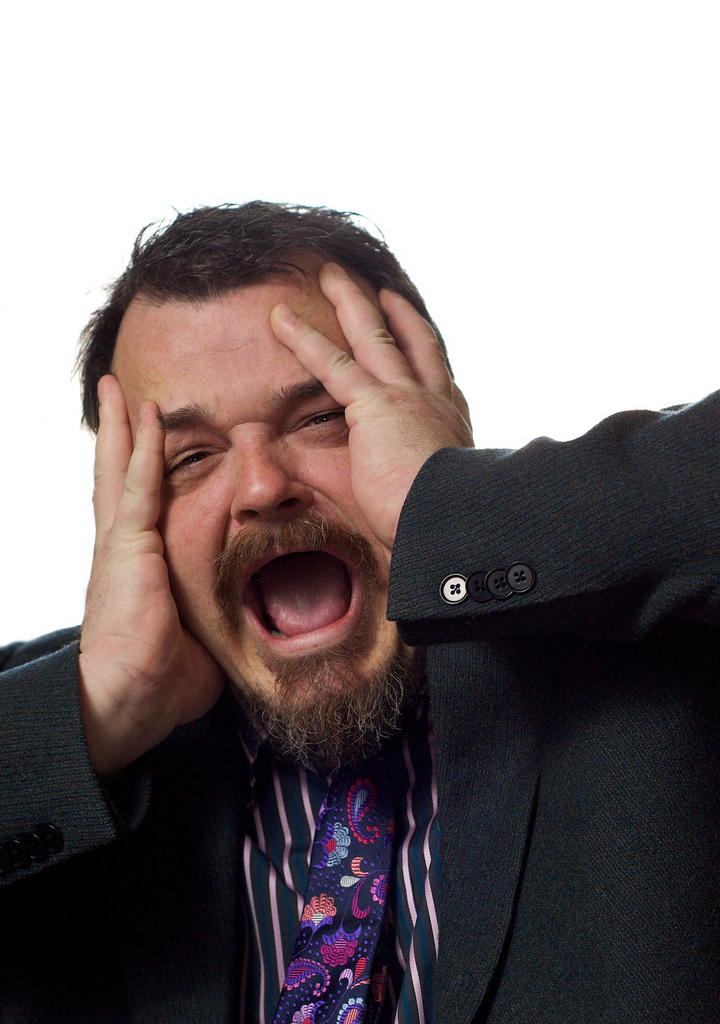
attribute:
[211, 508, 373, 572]
mustache — brown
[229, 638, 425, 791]
chin hair — brown, medium length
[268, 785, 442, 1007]
tie — multi-colored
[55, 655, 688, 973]
shirt — striped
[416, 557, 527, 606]
buttons — black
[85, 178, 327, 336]
hair — short and brown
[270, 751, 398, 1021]
tie — paisley , blue 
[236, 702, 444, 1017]
shirt — striped 